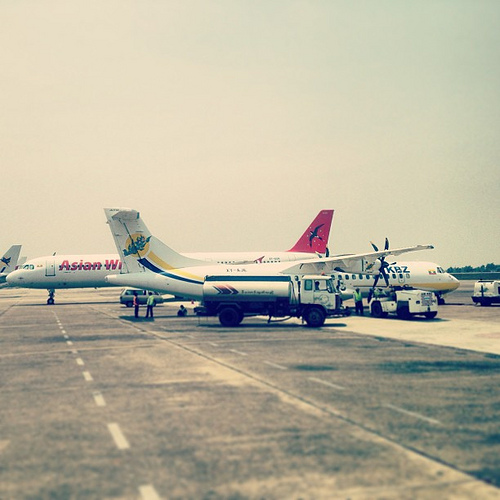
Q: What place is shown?
A: It is a runway.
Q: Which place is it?
A: It is a runway.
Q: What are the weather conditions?
A: It is clear.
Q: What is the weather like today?
A: It is clear.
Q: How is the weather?
A: It is clear.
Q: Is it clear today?
A: Yes, it is clear.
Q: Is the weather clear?
A: Yes, it is clear.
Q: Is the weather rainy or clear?
A: It is clear.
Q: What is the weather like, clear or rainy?
A: It is clear.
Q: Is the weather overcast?
A: No, it is clear.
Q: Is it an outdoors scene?
A: Yes, it is outdoors.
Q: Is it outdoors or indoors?
A: It is outdoors.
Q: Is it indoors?
A: No, it is outdoors.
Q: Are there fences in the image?
A: No, there are no fences.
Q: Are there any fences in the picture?
A: No, there are no fences.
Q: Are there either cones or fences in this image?
A: No, there are no fences or cones.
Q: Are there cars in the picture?
A: No, there are no cars.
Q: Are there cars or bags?
A: No, there are no cars or bags.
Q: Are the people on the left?
A: Yes, the people are on the left of the image.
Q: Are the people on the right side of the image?
A: No, the people are on the left of the image.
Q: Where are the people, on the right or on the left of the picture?
A: The people are on the left of the image.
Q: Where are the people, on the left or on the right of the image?
A: The people are on the left of the image.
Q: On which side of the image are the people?
A: The people are on the left of the image.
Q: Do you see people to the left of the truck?
A: Yes, there are people to the left of the truck.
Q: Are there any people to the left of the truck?
A: Yes, there are people to the left of the truck.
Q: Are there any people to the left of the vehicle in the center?
A: Yes, there are people to the left of the truck.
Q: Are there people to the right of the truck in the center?
A: No, the people are to the left of the truck.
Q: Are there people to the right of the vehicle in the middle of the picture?
A: No, the people are to the left of the truck.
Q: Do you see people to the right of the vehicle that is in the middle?
A: No, the people are to the left of the truck.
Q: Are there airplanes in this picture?
A: Yes, there is an airplane.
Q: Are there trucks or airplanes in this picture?
A: Yes, there is an airplane.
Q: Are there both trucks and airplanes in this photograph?
A: Yes, there are both an airplane and a truck.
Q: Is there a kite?
A: No, there are no kites.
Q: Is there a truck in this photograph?
A: Yes, there is a truck.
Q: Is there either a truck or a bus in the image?
A: Yes, there is a truck.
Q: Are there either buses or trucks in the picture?
A: Yes, there is a truck.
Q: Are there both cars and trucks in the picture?
A: No, there is a truck but no cars.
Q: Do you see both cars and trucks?
A: No, there is a truck but no cars.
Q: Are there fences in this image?
A: No, there are no fences.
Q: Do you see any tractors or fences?
A: No, there are no fences or tractors.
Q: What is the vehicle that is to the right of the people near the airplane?
A: The vehicle is a truck.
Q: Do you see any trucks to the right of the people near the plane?
A: Yes, there is a truck to the right of the people.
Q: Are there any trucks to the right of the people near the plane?
A: Yes, there is a truck to the right of the people.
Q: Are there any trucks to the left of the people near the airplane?
A: No, the truck is to the right of the people.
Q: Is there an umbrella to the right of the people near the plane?
A: No, there is a truck to the right of the people.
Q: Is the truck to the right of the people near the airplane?
A: Yes, the truck is to the right of the people.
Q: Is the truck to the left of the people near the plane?
A: No, the truck is to the right of the people.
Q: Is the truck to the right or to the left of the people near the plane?
A: The truck is to the right of the people.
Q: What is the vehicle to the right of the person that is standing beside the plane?
A: The vehicle is a truck.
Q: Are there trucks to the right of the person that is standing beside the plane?
A: Yes, there is a truck to the right of the person.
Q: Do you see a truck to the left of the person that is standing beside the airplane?
A: No, the truck is to the right of the person.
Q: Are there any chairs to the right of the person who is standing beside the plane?
A: No, there is a truck to the right of the person.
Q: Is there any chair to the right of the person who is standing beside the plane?
A: No, there is a truck to the right of the person.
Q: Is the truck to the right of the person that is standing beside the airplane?
A: Yes, the truck is to the right of the person.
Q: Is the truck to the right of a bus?
A: No, the truck is to the right of the person.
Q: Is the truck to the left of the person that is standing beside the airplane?
A: No, the truck is to the right of the person.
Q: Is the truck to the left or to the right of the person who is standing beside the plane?
A: The truck is to the right of the person.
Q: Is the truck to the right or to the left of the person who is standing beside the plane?
A: The truck is to the right of the person.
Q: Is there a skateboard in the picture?
A: No, there are no skateboards.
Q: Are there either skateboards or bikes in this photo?
A: No, there are no skateboards or bikes.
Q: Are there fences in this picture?
A: No, there are no fences.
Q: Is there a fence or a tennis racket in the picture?
A: No, there are no fences or rackets.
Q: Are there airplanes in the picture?
A: Yes, there is an airplane.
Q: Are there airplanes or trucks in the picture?
A: Yes, there is an airplane.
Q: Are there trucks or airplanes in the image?
A: Yes, there is an airplane.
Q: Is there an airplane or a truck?
A: Yes, there is an airplane.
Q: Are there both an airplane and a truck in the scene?
A: Yes, there are both an airplane and a truck.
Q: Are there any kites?
A: No, there are no kites.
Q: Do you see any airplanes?
A: Yes, there is an airplane.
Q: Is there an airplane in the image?
A: Yes, there is an airplane.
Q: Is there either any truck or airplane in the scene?
A: Yes, there is an airplane.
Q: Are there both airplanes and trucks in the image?
A: Yes, there are both an airplane and a truck.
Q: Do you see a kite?
A: No, there are no kites.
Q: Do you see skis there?
A: No, there are no skis.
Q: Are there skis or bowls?
A: No, there are no skis or bowls.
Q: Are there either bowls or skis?
A: No, there are no skis or bowls.